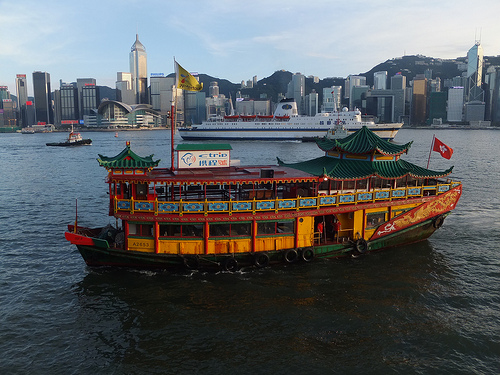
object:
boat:
[177, 90, 408, 144]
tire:
[218, 255, 243, 275]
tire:
[301, 245, 317, 263]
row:
[202, 246, 319, 274]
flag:
[425, 136, 457, 163]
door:
[267, 201, 367, 251]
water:
[0, 259, 499, 370]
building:
[325, 57, 480, 141]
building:
[57, 85, 99, 122]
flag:
[170, 59, 210, 97]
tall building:
[65, 130, 384, 265]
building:
[380, 72, 413, 122]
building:
[129, 39, 149, 104]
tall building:
[127, 32, 149, 104]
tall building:
[408, 74, 433, 124]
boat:
[62, 124, 486, 300]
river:
[1, 127, 497, 371]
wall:
[370, 90, 404, 119]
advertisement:
[179, 151, 231, 171]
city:
[0, 19, 496, 157]